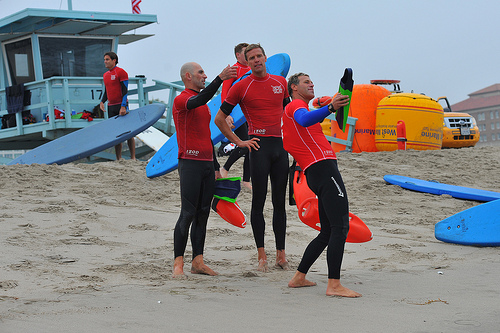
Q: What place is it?
A: It is a beach.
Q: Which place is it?
A: It is a beach.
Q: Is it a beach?
A: Yes, it is a beach.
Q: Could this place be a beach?
A: Yes, it is a beach.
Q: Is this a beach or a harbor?
A: It is a beach.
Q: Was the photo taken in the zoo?
A: No, the picture was taken in the beach.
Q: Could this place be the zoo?
A: No, it is the beach.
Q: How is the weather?
A: It is cloudy.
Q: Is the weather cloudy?
A: Yes, it is cloudy.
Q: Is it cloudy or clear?
A: It is cloudy.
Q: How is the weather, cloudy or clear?
A: It is cloudy.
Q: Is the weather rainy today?
A: No, it is cloudy.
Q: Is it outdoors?
A: Yes, it is outdoors.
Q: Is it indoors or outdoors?
A: It is outdoors.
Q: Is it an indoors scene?
A: No, it is outdoors.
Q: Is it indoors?
A: No, it is outdoors.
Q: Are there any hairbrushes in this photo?
A: No, there are no hairbrushes.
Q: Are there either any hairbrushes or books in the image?
A: No, there are no hairbrushes or books.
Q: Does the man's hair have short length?
A: Yes, the hair is short.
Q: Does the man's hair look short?
A: Yes, the hair is short.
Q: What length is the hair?
A: The hair is short.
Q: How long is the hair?
A: The hair is short.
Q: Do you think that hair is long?
A: No, the hair is short.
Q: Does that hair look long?
A: No, the hair is short.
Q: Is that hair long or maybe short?
A: The hair is short.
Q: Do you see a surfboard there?
A: Yes, there is a surfboard.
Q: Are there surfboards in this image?
A: Yes, there is a surfboard.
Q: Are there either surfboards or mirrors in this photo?
A: Yes, there is a surfboard.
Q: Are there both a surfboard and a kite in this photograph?
A: No, there is a surfboard but no kites.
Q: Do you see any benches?
A: No, there are no benches.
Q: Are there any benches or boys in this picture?
A: No, there are no benches or boys.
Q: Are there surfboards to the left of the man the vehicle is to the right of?
A: Yes, there is a surfboard to the left of the man.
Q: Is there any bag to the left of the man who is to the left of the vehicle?
A: No, there is a surfboard to the left of the man.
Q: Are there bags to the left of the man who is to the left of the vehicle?
A: No, there is a surfboard to the left of the man.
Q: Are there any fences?
A: No, there are no fences.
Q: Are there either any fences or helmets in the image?
A: No, there are no fences or helmets.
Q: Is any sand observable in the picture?
A: Yes, there is sand.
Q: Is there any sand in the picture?
A: Yes, there is sand.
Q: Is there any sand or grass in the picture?
A: Yes, there is sand.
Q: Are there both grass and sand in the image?
A: No, there is sand but no grass.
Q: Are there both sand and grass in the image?
A: No, there is sand but no grass.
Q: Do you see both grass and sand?
A: No, there is sand but no grass.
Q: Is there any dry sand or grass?
A: Yes, there is dry sand.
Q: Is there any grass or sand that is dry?
A: Yes, the sand is dry.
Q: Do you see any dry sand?
A: Yes, there is dry sand.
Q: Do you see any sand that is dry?
A: Yes, there is sand that is dry.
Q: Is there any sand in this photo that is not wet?
A: Yes, there is dry sand.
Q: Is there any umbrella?
A: No, there are no umbrellas.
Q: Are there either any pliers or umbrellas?
A: No, there are no umbrellas or pliers.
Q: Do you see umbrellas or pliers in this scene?
A: No, there are no umbrellas or pliers.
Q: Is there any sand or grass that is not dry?
A: No, there is sand but it is dry.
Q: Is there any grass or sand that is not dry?
A: No, there is sand but it is dry.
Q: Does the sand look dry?
A: Yes, the sand is dry.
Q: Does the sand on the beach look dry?
A: Yes, the sand is dry.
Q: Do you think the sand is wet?
A: No, the sand is dry.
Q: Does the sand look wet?
A: No, the sand is dry.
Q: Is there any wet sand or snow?
A: No, there is sand but it is dry.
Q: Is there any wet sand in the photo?
A: No, there is sand but it is dry.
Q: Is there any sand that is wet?
A: No, there is sand but it is dry.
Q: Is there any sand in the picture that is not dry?
A: No, there is sand but it is dry.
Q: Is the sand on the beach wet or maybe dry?
A: The sand is dry.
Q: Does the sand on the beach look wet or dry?
A: The sand is dry.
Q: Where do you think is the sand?
A: The sand is on the beach.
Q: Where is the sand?
A: The sand is on the beach.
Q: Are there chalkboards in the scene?
A: No, there are no chalkboards.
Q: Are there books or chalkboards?
A: No, there are no chalkboards or books.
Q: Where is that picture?
A: The picture is on the beach.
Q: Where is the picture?
A: The picture is on the beach.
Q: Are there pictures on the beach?
A: Yes, there is a picture on the beach.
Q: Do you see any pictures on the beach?
A: Yes, there is a picture on the beach.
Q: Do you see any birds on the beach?
A: No, there is a picture on the beach.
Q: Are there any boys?
A: No, there are no boys.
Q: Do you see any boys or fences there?
A: No, there are no boys or fences.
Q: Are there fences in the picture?
A: No, there are no fences.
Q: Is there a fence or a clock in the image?
A: No, there are no fences or clocks.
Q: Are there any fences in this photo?
A: No, there are no fences.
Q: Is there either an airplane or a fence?
A: No, there are no fences or airplanes.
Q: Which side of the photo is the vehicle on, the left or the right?
A: The vehicle is on the right of the image.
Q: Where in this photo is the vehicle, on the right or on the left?
A: The vehicle is on the right of the image.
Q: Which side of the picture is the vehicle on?
A: The vehicle is on the right of the image.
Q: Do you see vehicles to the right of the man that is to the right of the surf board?
A: Yes, there is a vehicle to the right of the man.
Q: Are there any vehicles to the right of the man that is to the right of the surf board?
A: Yes, there is a vehicle to the right of the man.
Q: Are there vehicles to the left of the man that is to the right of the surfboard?
A: No, the vehicle is to the right of the man.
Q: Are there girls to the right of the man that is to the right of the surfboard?
A: No, there is a vehicle to the right of the man.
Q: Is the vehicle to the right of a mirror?
A: No, the vehicle is to the right of a man.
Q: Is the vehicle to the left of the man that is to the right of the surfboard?
A: No, the vehicle is to the right of the man.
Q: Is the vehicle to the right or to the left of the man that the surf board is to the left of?
A: The vehicle is to the right of the man.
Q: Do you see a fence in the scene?
A: No, there are no fences.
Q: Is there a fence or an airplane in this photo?
A: No, there are no fences or airplanes.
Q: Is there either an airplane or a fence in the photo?
A: No, there are no fences or airplanes.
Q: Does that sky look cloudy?
A: Yes, the sky is cloudy.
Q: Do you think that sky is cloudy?
A: Yes, the sky is cloudy.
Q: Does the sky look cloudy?
A: Yes, the sky is cloudy.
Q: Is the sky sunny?
A: No, the sky is cloudy.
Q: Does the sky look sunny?
A: No, the sky is cloudy.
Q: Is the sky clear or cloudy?
A: The sky is cloudy.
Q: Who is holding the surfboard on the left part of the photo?
A: The man is holding the surfboard.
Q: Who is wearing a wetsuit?
A: The man is wearing a wetsuit.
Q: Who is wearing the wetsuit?
A: The man is wearing a wetsuit.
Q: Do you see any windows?
A: Yes, there are windows.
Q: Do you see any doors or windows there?
A: Yes, there are windows.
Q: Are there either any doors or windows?
A: Yes, there are windows.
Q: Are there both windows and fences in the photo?
A: No, there are windows but no fences.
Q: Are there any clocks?
A: No, there are no clocks.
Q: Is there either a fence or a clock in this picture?
A: No, there are no clocks or fences.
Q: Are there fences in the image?
A: No, there are no fences.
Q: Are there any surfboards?
A: Yes, there is a surfboard.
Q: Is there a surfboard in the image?
A: Yes, there is a surfboard.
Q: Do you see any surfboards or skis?
A: Yes, there is a surfboard.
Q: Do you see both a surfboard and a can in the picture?
A: No, there is a surfboard but no cans.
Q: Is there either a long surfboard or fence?
A: Yes, there is a long surfboard.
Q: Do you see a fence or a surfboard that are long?
A: Yes, the surfboard is long.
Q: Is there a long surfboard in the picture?
A: Yes, there is a long surfboard.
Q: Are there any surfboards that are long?
A: Yes, there is a surfboard that is long.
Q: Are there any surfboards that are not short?
A: Yes, there is a long surfboard.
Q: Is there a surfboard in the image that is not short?
A: Yes, there is a long surfboard.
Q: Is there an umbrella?
A: No, there are no umbrellas.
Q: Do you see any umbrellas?
A: No, there are no umbrellas.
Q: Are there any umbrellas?
A: No, there are no umbrellas.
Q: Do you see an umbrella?
A: No, there are no umbrellas.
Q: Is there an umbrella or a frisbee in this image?
A: No, there are no umbrellas or frisbees.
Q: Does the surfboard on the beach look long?
A: Yes, the surfboard is long.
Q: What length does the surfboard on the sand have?
A: The surfboard has long length.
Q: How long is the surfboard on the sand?
A: The surfboard is long.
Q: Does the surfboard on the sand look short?
A: No, the surfboard is long.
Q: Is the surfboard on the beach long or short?
A: The surfboard is long.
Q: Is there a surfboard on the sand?
A: Yes, there is a surfboard on the sand.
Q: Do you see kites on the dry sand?
A: No, there is a surfboard on the sand.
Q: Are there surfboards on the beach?
A: Yes, there is a surfboard on the beach.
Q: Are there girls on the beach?
A: No, there is a surfboard on the beach.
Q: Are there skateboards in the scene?
A: No, there are no skateboards.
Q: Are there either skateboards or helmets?
A: No, there are no skateboards or helmets.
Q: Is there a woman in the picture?
A: No, there are no women.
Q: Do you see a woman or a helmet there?
A: No, there are no women or helmets.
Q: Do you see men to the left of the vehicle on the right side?
A: Yes, there is a man to the left of the vehicle.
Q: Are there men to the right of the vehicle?
A: No, the man is to the left of the vehicle.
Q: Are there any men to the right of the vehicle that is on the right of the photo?
A: No, the man is to the left of the vehicle.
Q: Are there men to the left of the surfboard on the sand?
A: Yes, there is a man to the left of the surfboard.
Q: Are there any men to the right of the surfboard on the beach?
A: No, the man is to the left of the surfboard.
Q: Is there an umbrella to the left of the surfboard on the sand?
A: No, there is a man to the left of the surfboard.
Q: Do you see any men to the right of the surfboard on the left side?
A: Yes, there is a man to the right of the surfboard.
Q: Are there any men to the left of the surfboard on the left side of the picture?
A: No, the man is to the right of the surfboard.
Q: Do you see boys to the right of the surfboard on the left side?
A: No, there is a man to the right of the surfboard.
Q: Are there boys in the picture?
A: No, there are no boys.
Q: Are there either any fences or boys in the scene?
A: No, there are no boys or fences.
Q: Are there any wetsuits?
A: Yes, there is a wetsuit.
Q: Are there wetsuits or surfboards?
A: Yes, there is a wetsuit.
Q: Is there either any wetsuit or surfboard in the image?
A: Yes, there is a wetsuit.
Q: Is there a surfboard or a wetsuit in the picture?
A: Yes, there is a wetsuit.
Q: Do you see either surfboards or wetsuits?
A: Yes, there is a wetsuit.